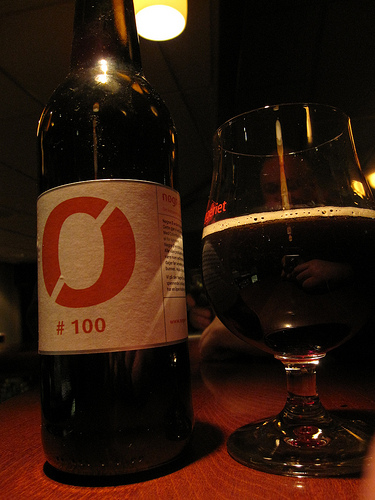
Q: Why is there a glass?
A: Beer.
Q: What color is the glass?
A: Clear.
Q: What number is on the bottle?
A: 100.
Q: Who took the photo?
A: Drinker.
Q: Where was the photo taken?
A: Bar.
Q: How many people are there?
A: 0.